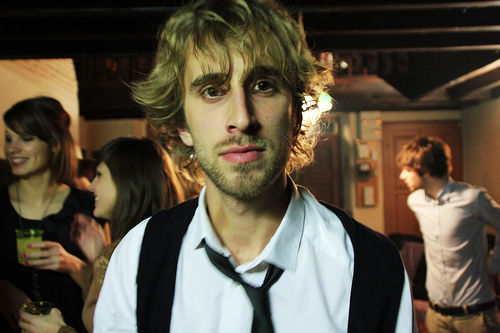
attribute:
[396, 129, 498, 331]
pants — tan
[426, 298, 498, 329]
man — young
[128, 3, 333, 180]
hair — blonde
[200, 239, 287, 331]
tie — black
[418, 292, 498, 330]
pants —  khaki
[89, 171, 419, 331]
shirt — white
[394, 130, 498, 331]
man — standing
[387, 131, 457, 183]
hair — red 